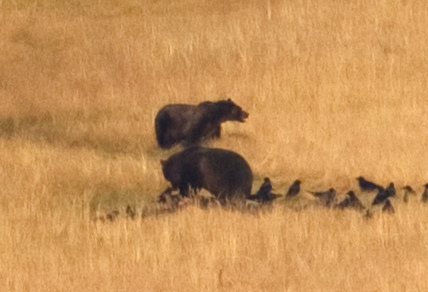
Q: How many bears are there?
A: Two.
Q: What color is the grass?
A: Yellow.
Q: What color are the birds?
A: Black.